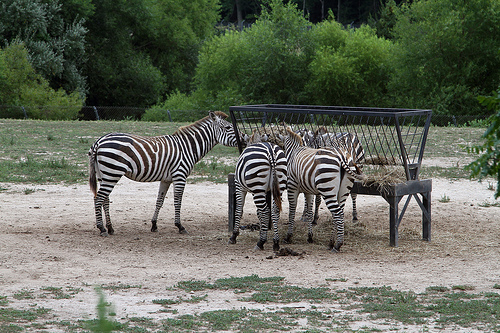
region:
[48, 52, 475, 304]
the zebras are eating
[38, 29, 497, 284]
a small herd of zebras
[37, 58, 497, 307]
the species is zebra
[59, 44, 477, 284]
the trough is black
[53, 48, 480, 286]
zebras eating hay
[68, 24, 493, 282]
zebras are black and white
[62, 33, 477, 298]
there are four zebras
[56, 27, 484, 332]
the zebras have stripes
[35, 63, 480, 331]
the ground is patchy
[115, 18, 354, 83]
the leaves are green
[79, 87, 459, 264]
zebras feeding in a field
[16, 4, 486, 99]
green trees in the background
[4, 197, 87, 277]
dirt ground where zebras are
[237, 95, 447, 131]
black metal feeding contraption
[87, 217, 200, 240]
hooves of a zebra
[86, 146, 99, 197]
tail of a zebra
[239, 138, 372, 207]
behinds of two zebras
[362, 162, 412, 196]
hay for zebras to eat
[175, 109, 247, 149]
face and mane of a zebra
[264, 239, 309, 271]
zebra feces on the ground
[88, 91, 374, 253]
a group of zebras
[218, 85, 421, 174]
a device for feeding the zebras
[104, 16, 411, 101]
some trees in the background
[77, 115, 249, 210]
a zebra standing on the right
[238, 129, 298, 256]
the middle zebra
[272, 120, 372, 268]
the zebra on the right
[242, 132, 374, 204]
2 zebra buts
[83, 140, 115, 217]
the tail of a zebra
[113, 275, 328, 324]
specks of grass on the ground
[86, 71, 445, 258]
a group of zebras eating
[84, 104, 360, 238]
Zebras feasting on hay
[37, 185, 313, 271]
A sandy area around the feeding trough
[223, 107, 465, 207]
A feeding trough with hay for zebras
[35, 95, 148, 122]
A fence boarding the zebra pen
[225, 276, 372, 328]
Green growth in the sand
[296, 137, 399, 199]
A swinging zebra tail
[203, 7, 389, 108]
Green leafy trees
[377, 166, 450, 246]
Support for the feeding trough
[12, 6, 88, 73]
A large pine tree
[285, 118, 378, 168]
A zebra behind the feeding trough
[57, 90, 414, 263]
Zebras are eating.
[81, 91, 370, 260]
Zebras are black and white.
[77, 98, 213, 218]
The zebra is striped.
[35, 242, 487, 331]
Grass patches on the ground.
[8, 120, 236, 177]
The grass is green.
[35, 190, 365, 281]
The dirt is brown.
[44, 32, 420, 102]
the trees are green.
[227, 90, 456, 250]
The feeder is black.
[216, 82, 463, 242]
The feeder is metal.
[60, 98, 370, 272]
The zebras are standing in dirt.